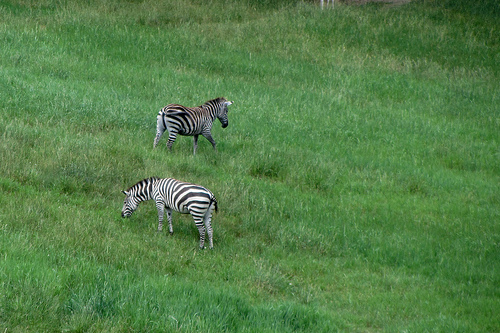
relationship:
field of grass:
[1, 1, 499, 331] [65, 278, 159, 332]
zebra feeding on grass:
[121, 175, 217, 250] [65, 278, 159, 332]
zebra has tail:
[121, 175, 217, 250] [212, 196, 219, 215]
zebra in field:
[121, 175, 217, 250] [1, 1, 499, 331]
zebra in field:
[153, 96, 233, 155] [1, 1, 499, 331]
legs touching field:
[152, 130, 200, 156] [1, 1, 499, 331]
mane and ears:
[129, 173, 161, 192] [121, 188, 130, 198]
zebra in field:
[121, 176, 222, 251] [1, 1, 499, 331]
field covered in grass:
[1, 1, 499, 331] [65, 278, 159, 332]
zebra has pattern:
[153, 96, 233, 155] [191, 113, 207, 127]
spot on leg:
[168, 212, 172, 218] [166, 207, 176, 237]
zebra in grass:
[121, 176, 222, 251] [65, 278, 159, 332]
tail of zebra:
[212, 196, 219, 215] [121, 175, 217, 250]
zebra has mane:
[121, 175, 217, 250] [126, 175, 161, 192]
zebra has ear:
[153, 96, 233, 155] [226, 99, 235, 108]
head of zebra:
[119, 190, 140, 223] [121, 175, 217, 250]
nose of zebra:
[121, 210, 125, 219] [121, 175, 217, 250]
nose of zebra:
[222, 122, 230, 129] [153, 96, 233, 155]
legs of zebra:
[154, 202, 216, 251] [121, 175, 217, 250]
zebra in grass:
[121, 175, 217, 250] [65, 278, 159, 332]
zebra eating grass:
[121, 175, 217, 250] [65, 278, 159, 332]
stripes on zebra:
[160, 186, 187, 206] [121, 175, 217, 250]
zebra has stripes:
[121, 175, 217, 250] [160, 186, 187, 206]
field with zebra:
[1, 1, 499, 331] [121, 176, 222, 251]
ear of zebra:
[226, 99, 235, 108] [153, 96, 233, 155]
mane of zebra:
[129, 173, 161, 192] [121, 175, 217, 250]